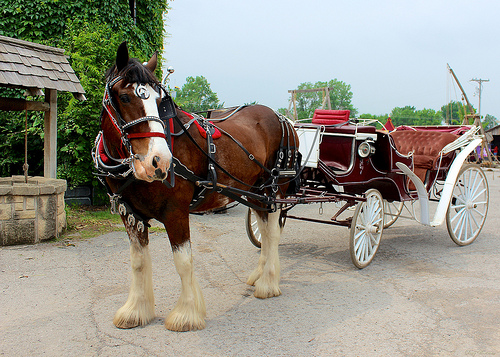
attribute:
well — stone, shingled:
[3, 32, 83, 249]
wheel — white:
[343, 187, 389, 271]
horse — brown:
[81, 38, 298, 330]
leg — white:
[169, 237, 212, 333]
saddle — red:
[183, 109, 222, 141]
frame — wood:
[286, 84, 338, 120]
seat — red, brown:
[387, 124, 457, 167]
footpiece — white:
[391, 137, 488, 228]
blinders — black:
[156, 96, 175, 121]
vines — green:
[17, 5, 149, 44]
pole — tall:
[471, 72, 491, 119]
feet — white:
[157, 263, 202, 333]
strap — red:
[123, 129, 168, 142]